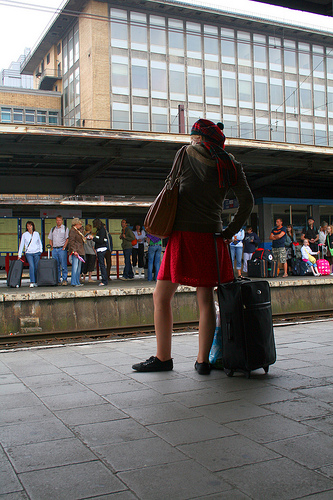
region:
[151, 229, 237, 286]
red skirt on the woman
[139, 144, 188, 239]
brown purse on the woman's shoulder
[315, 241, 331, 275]
pink suitcase in the girl's hand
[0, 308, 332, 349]
brown train tracks along the walkway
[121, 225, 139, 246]
red backpack on the person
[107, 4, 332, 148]
windows on the building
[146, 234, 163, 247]
green shirt on the person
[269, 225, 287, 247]
navy blue shirt with orange logo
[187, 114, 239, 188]
blue, green and red beanie and scarf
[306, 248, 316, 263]
yellow bag in the girl's lap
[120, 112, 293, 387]
The woman is holding onto her luggage.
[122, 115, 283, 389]
The woman is wearing a plaid cap.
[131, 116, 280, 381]
The woman is wearing a plaid scarf.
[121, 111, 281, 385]
The woman is wearing black shoes.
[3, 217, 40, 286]
The woman is holding onto her luggage.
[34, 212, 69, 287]
The man is standing behind his luggage.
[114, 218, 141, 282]
The man is wearing a backpack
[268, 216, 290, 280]
The man's arms are crossed in front of him.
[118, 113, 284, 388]
The woman has a brown shoulder bag.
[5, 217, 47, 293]
The woman is wearing blue jeans.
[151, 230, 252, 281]
the skirt is red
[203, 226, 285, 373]
the suitcase is black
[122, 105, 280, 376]
woman with suitcase on platform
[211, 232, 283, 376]
suitcase on wheels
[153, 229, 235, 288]
skirt on the woman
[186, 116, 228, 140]
hat on the woman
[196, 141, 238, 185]
scarf on the woman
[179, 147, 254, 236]
top on the woman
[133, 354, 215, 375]
shoes on the woman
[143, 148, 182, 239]
bag on the woman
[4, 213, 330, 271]
people on the platform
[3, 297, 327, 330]
tracks where train travels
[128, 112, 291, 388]
woman in hat with rolling bag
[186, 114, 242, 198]
matching hat and scarf on woman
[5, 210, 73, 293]
people in jeans with rolling luggage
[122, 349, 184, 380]
black show on left foot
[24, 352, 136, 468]
cement tiled sidewalk on train platform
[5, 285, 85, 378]
train tracks in between two platforms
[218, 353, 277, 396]
wheels on bottom of rolling luggage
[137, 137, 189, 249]
brown leather shoulder bag on woman's arm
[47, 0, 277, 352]
building above the train station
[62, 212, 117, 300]
people talking on the train platform